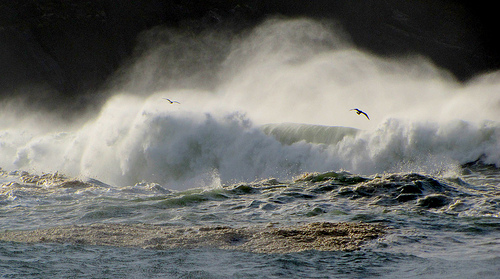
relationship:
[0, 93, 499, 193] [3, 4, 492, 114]
wave breaks on rock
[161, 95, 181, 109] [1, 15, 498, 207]
seagull over wave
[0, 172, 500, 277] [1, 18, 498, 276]
light on water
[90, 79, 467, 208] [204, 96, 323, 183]
splash of water